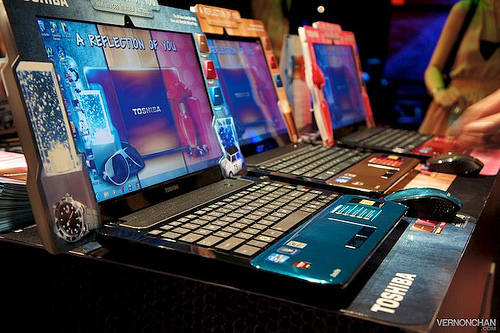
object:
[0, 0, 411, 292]
laptop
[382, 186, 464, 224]
mouse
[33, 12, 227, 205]
screen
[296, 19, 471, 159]
computer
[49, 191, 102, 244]
compass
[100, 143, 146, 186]
sunglasses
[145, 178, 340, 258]
keyboard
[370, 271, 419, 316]
logo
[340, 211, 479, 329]
pad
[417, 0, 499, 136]
lady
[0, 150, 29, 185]
paper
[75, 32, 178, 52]
wording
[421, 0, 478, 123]
purse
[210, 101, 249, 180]
car